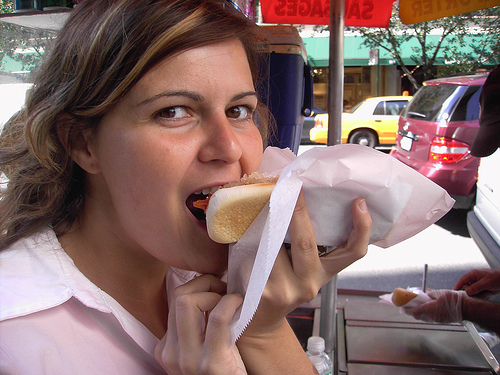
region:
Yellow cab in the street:
[315, 88, 412, 144]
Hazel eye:
[158, 106, 185, 121]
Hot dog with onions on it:
[204, 170, 454, 242]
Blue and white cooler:
[258, 18, 310, 150]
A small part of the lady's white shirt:
[9, 283, 86, 373]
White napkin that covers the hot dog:
[219, 235, 281, 330]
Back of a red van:
[393, 78, 473, 195]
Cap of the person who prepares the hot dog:
[467, 66, 499, 165]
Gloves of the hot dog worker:
[414, 287, 463, 328]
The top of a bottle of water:
[301, 337, 338, 372]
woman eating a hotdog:
[20, 12, 446, 272]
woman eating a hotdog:
[56, 3, 266, 303]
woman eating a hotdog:
[16, 117, 308, 303]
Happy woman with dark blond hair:
[0, 0, 374, 370]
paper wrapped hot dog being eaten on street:
[194, 155, 444, 250]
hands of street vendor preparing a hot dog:
[393, 266, 496, 329]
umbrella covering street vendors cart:
[251, 0, 498, 37]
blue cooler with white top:
[252, 26, 314, 151]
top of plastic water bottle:
[307, 335, 335, 374]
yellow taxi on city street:
[310, 89, 401, 151]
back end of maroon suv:
[389, 70, 483, 209]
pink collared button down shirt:
[0, 236, 172, 373]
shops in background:
[304, 19, 490, 129]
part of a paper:
[326, 158, 371, 187]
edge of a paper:
[243, 282, 266, 332]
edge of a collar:
[20, 295, 78, 324]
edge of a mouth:
[165, 192, 199, 220]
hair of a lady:
[13, 167, 80, 233]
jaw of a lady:
[134, 232, 182, 277]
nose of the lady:
[216, 116, 242, 166]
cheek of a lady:
[144, 147, 182, 172]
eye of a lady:
[226, 92, 253, 128]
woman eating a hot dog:
[64, 10, 414, 360]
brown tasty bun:
[213, 194, 248, 234]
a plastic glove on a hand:
[430, 280, 461, 323]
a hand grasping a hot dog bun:
[382, 277, 484, 332]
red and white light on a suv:
[422, 128, 468, 167]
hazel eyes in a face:
[149, 97, 252, 129]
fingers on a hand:
[293, 208, 368, 260]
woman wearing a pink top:
[19, 17, 269, 374]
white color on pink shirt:
[8, 247, 53, 297]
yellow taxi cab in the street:
[343, 88, 391, 125]